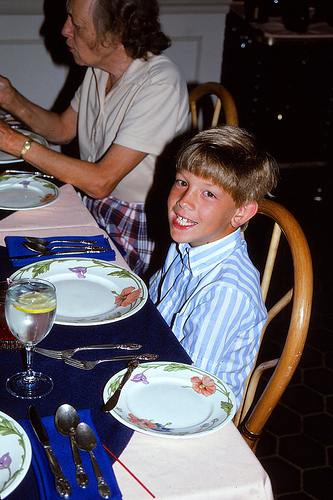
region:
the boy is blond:
[141, 122, 287, 386]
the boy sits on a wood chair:
[137, 126, 315, 430]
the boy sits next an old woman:
[1, 6, 310, 407]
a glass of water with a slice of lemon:
[2, 270, 60, 405]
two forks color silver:
[32, 336, 159, 375]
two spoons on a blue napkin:
[52, 397, 113, 498]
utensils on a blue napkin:
[1, 228, 118, 262]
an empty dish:
[13, 248, 152, 333]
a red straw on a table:
[96, 439, 164, 498]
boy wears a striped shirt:
[135, 117, 274, 430]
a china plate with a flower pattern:
[101, 361, 238, 438]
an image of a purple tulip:
[131, 372, 148, 383]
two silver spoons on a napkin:
[54, 403, 112, 498]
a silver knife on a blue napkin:
[27, 403, 72, 499]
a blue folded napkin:
[15, 409, 127, 498]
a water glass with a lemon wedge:
[6, 275, 58, 399]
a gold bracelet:
[17, 133, 35, 157]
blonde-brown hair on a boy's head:
[175, 125, 276, 208]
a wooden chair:
[231, 197, 311, 451]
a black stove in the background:
[228, 0, 332, 207]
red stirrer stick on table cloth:
[103, 443, 156, 499]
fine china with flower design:
[103, 362, 238, 438]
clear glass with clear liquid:
[3, 277, 53, 398]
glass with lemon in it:
[5, 276, 57, 399]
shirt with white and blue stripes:
[149, 228, 267, 409]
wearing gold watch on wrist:
[18, 133, 33, 159]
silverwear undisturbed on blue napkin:
[3, 234, 116, 262]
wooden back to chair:
[232, 197, 313, 451]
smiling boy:
[165, 124, 275, 244]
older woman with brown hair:
[61, 0, 172, 66]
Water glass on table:
[5, 278, 63, 403]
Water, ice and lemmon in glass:
[4, 273, 56, 402]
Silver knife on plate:
[96, 352, 140, 417]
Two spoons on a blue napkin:
[53, 397, 115, 499]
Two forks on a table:
[31, 340, 164, 369]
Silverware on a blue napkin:
[2, 228, 117, 268]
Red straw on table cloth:
[95, 432, 159, 498]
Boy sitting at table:
[120, 123, 286, 382]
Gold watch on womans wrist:
[9, 130, 37, 165]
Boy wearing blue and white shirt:
[126, 240, 266, 402]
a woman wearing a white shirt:
[0, 1, 188, 278]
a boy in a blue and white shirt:
[146, 128, 276, 417]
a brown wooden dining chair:
[239, 200, 310, 445]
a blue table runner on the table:
[1, 247, 192, 498]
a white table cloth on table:
[1, 182, 274, 498]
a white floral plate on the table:
[102, 361, 234, 436]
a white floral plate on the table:
[4, 257, 140, 321]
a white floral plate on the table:
[0, 170, 58, 206]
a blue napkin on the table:
[31, 409, 120, 498]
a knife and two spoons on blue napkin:
[26, 402, 113, 499]